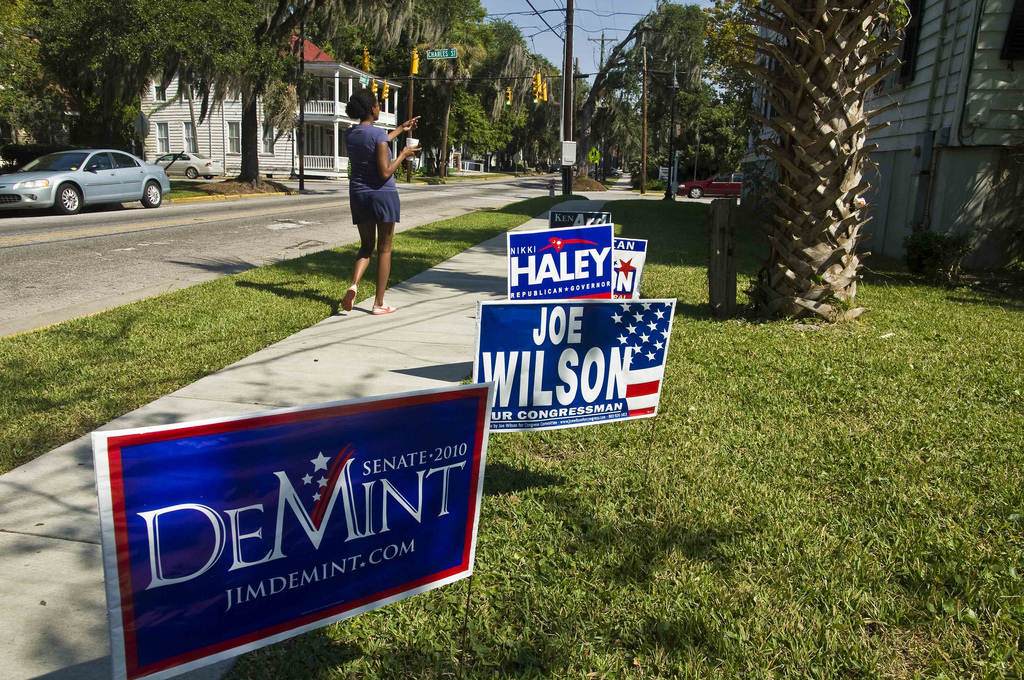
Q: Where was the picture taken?
A: It was taken at the sidewalk.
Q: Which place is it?
A: It is a sidewalk.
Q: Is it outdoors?
A: Yes, it is outdoors.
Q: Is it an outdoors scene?
A: Yes, it is outdoors.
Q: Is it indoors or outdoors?
A: It is outdoors.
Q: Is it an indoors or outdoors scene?
A: It is outdoors.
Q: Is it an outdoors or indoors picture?
A: It is outdoors.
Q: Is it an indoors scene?
A: No, it is outdoors.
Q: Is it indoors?
A: No, it is outdoors.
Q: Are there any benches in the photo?
A: No, there are no benches.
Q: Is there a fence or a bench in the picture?
A: No, there are no benches or fences.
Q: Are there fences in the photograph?
A: No, there are no fences.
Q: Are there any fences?
A: No, there are no fences.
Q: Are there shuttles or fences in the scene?
A: No, there are no fences or shuttles.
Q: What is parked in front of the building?
A: The car is parked in front of the building.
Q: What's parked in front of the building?
A: The car is parked in front of the building.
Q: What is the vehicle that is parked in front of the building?
A: The vehicle is a car.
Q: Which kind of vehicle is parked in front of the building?
A: The vehicle is a car.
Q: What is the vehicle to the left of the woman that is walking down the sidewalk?
A: The vehicle is a car.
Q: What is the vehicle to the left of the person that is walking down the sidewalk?
A: The vehicle is a car.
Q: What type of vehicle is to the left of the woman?
A: The vehicle is a car.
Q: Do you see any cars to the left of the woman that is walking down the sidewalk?
A: Yes, there is a car to the left of the woman.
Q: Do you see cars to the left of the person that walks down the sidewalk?
A: Yes, there is a car to the left of the woman.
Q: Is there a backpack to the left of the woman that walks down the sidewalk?
A: No, there is a car to the left of the woman.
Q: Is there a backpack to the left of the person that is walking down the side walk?
A: No, there is a car to the left of the woman.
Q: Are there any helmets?
A: No, there are no helmets.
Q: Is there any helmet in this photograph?
A: No, there are no helmets.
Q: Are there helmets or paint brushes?
A: No, there are no helmets or paint brushes.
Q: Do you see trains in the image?
A: No, there are no trains.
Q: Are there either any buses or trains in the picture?
A: No, there are no trains or buses.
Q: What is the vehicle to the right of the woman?
A: The vehicle is a car.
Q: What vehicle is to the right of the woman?
A: The vehicle is a car.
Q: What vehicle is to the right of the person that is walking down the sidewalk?
A: The vehicle is a car.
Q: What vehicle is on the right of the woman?
A: The vehicle is a car.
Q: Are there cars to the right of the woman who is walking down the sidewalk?
A: Yes, there is a car to the right of the woman.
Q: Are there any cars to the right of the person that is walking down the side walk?
A: Yes, there is a car to the right of the woman.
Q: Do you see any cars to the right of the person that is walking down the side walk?
A: Yes, there is a car to the right of the woman.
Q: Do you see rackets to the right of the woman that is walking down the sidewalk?
A: No, there is a car to the right of the woman.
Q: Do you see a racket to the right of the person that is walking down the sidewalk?
A: No, there is a car to the right of the woman.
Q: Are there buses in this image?
A: No, there are no buses.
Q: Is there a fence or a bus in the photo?
A: No, there are no buses or fences.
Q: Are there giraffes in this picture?
A: No, there are no giraffes.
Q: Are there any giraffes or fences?
A: No, there are no giraffes or fences.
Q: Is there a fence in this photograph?
A: No, there are no fences.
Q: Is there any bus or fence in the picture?
A: No, there are no fences or buses.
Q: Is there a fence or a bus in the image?
A: No, there are no fences or buses.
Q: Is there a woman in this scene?
A: Yes, there is a woman.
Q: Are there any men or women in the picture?
A: Yes, there is a woman.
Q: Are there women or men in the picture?
A: Yes, there is a woman.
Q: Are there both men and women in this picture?
A: No, there is a woman but no men.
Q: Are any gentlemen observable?
A: No, there are no gentlemen.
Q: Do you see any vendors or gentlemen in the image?
A: No, there are no gentlemen or vendors.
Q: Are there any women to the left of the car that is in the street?
A: No, the woman is to the right of the car.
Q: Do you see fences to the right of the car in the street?
A: No, there is a woman to the right of the car.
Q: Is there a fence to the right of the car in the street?
A: No, there is a woman to the right of the car.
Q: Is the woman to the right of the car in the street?
A: Yes, the woman is to the right of the car.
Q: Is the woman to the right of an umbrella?
A: No, the woman is to the right of the car.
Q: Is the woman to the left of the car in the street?
A: No, the woman is to the right of the car.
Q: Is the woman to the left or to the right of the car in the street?
A: The woman is to the right of the car.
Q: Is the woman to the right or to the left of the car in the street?
A: The woman is to the right of the car.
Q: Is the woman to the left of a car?
A: Yes, the woman is to the left of a car.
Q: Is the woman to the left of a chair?
A: No, the woman is to the left of a car.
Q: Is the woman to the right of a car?
A: Yes, the woman is to the right of a car.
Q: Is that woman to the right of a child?
A: No, the woman is to the right of a car.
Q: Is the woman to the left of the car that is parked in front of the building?
A: No, the woman is to the right of the car.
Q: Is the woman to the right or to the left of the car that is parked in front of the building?
A: The woman is to the right of the car.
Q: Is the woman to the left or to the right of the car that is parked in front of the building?
A: The woman is to the right of the car.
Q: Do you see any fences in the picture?
A: No, there are no fences.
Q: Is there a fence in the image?
A: No, there are no fences.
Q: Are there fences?
A: No, there are no fences.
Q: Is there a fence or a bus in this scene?
A: No, there are no fences or buses.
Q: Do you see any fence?
A: No, there are no fences.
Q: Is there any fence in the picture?
A: No, there are no fences.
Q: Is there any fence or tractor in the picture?
A: No, there are no fences or tractors.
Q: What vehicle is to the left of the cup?
A: The vehicle is a car.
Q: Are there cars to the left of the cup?
A: Yes, there is a car to the left of the cup.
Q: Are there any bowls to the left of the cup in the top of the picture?
A: No, there is a car to the left of the cup.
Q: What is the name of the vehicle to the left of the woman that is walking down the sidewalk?
A: The vehicle is a car.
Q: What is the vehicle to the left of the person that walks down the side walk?
A: The vehicle is a car.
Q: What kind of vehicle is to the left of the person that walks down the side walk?
A: The vehicle is a car.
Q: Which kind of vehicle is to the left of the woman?
A: The vehicle is a car.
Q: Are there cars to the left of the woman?
A: Yes, there is a car to the left of the woman.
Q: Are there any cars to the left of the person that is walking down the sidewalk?
A: Yes, there is a car to the left of the woman.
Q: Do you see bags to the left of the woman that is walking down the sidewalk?
A: No, there is a car to the left of the woman.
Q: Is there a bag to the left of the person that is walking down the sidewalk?
A: No, there is a car to the left of the woman.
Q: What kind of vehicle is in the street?
A: The vehicle is a car.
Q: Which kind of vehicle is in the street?
A: The vehicle is a car.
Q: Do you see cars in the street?
A: Yes, there is a car in the street.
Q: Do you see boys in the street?
A: No, there is a car in the street.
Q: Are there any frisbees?
A: No, there are no frisbees.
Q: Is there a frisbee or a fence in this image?
A: No, there are no frisbees or fences.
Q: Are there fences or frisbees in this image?
A: No, there are no frisbees or fences.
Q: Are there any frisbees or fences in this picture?
A: No, there are no frisbees or fences.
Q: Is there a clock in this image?
A: No, there are no clocks.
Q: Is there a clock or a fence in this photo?
A: No, there are no clocks or fences.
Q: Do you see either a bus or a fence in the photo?
A: No, there are no fences or buses.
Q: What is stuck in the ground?
A: The sign is stuck in the ground.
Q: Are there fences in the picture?
A: No, there are no fences.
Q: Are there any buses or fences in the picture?
A: No, there are no fences or buses.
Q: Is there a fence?
A: No, there are no fences.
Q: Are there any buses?
A: No, there are no buses.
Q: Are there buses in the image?
A: No, there are no buses.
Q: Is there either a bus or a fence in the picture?
A: No, there are no buses or fences.